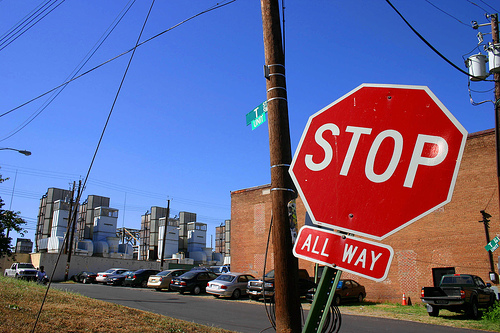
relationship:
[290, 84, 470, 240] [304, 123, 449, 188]
sign says stop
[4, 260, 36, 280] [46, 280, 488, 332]
truck on road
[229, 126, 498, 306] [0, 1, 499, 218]
building in distance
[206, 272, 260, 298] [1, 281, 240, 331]
car on grass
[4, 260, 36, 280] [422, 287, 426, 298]
truck has a tail light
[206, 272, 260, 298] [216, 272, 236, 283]
car has a rear window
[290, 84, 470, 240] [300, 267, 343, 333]
sign on a pole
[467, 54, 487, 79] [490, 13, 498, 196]
electric transformer on a pole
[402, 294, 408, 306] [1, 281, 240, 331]
traffic cone in grass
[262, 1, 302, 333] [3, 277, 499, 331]
post in ground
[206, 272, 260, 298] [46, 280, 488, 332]
car near road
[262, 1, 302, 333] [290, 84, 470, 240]
post has a sign